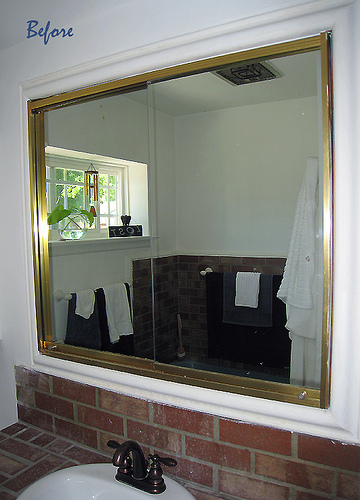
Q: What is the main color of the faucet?
A: Brown.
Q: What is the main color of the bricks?
A: Red.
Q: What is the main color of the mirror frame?
A: Gold.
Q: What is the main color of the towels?
A: White.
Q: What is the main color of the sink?
A: White.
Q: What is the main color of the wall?
A: White.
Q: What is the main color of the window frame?
A: White.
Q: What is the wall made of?
A: All sheetrock and brick.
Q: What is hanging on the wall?
A: A mirror.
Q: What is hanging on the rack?
A: A towel.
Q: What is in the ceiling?
A: A vent.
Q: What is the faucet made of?
A: Brass.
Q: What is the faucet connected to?
A: A sink.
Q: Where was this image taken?
A: In a bathroom.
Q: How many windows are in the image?
A: 1.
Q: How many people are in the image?
A: 0.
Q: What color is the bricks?
A: Red.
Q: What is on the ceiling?
A: A vent.